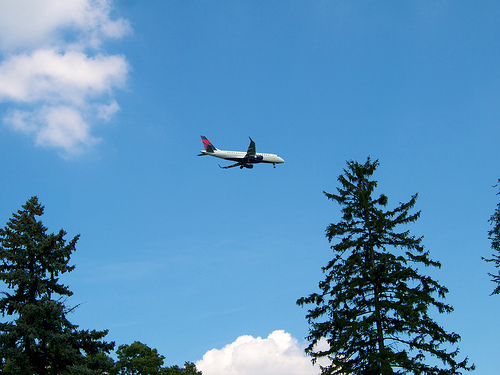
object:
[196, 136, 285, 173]
airplane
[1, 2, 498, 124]
sky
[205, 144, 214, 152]
tail fin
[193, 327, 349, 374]
cloud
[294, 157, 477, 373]
tree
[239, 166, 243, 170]
wheels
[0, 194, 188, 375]
trees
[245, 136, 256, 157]
wings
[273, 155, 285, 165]
nose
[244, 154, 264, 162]
engines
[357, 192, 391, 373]
trunk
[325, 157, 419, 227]
top